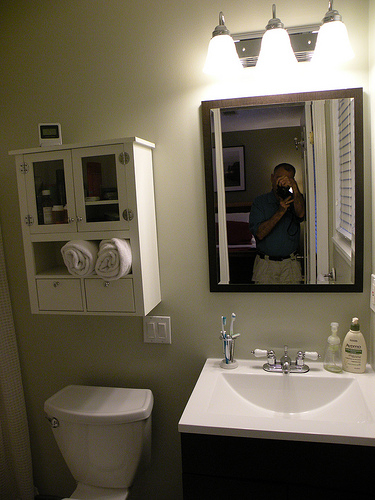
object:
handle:
[44, 415, 59, 428]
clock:
[38, 123, 63, 146]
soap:
[323, 364, 342, 373]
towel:
[94, 237, 133, 283]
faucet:
[280, 345, 292, 377]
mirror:
[208, 96, 356, 288]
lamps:
[201, 23, 244, 74]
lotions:
[341, 317, 367, 374]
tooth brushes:
[221, 316, 226, 359]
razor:
[231, 333, 241, 340]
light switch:
[140, 313, 172, 345]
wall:
[0, 0, 374, 499]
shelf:
[35, 265, 133, 276]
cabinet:
[70, 142, 131, 231]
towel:
[60, 238, 98, 275]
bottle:
[317, 319, 341, 374]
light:
[250, 18, 304, 78]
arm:
[249, 196, 294, 241]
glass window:
[32, 158, 69, 226]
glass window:
[80, 152, 121, 225]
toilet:
[42, 384, 154, 500]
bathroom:
[0, 0, 374, 500]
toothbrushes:
[230, 313, 237, 357]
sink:
[177, 356, 375, 446]